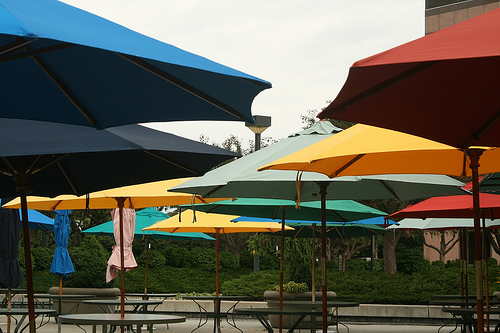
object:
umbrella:
[139, 209, 291, 236]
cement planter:
[48, 286, 123, 314]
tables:
[0, 308, 59, 333]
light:
[244, 115, 271, 134]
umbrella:
[181, 118, 468, 200]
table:
[23, 294, 99, 326]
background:
[0, 0, 500, 333]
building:
[426, 0, 498, 34]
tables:
[56, 313, 182, 333]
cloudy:
[0, 0, 427, 151]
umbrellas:
[255, 123, 498, 178]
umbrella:
[103, 206, 137, 283]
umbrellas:
[317, 7, 497, 149]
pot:
[264, 289, 336, 328]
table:
[80, 299, 166, 333]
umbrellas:
[0, 0, 272, 133]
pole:
[470, 154, 484, 333]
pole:
[319, 190, 327, 330]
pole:
[216, 228, 221, 317]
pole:
[456, 238, 473, 320]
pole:
[17, 178, 37, 333]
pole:
[115, 202, 126, 332]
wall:
[0, 293, 500, 326]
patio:
[0, 313, 480, 332]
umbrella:
[173, 196, 389, 223]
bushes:
[0, 205, 500, 306]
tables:
[234, 307, 343, 333]